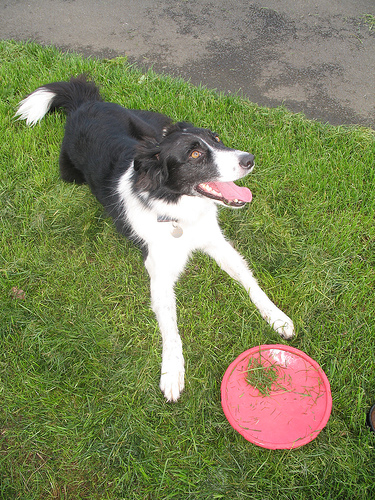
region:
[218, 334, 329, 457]
a pink plate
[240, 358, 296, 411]
grass on the plate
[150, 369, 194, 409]
paw on the grass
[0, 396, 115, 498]
patches of dirt in the grass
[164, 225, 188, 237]
tag for the collar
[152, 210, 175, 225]
the collar on the dog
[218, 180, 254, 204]
the dogs pink tounge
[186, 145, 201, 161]
the dogs brown eye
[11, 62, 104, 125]
the tail of the dog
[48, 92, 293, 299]
this is a dog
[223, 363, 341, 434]
this is a lid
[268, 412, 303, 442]
the lid is red in color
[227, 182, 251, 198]
this is the tongue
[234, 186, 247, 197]
the tongue is red in color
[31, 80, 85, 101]
this is the tail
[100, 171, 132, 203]
the dog is white and black in color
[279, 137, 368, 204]
this is the grass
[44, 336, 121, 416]
the grass is green in color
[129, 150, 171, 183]
this is the ear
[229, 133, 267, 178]
nose of the dog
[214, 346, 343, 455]
red toy next to dog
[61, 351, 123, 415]
grass next to the dog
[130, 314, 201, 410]
paw of the dog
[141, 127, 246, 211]
head of the dog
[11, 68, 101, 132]
tail of the dog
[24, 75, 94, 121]
black and white tail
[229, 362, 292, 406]
grass on the toy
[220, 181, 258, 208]
tongue of the dog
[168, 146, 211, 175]
eye of the dog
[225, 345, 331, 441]
red toy on ground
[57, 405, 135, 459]
green grass next to toy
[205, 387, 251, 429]
edge of the toy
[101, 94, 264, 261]
black and white dog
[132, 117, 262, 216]
dog looking up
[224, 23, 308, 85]
street next to grass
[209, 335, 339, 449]
A red dog toy.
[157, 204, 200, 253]
A round dog tag.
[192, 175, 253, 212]
A row of canine teeth.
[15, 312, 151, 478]
An area of green grass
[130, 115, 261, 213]
The head of a dog.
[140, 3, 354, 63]
An area of blacktop surface.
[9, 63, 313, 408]
A black and white dog.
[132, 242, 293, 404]
The front legs of the black and white dog.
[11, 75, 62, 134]
The white tip of the dog's tail.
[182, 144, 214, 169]
The right eye of the dog.